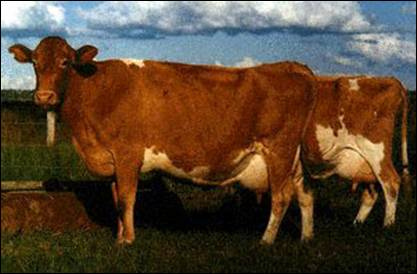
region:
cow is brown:
[8, 32, 335, 241]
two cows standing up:
[7, 38, 409, 247]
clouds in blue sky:
[77, 7, 398, 65]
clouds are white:
[80, 2, 400, 54]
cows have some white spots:
[7, 33, 406, 243]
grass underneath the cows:
[18, 167, 263, 262]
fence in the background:
[3, 86, 100, 218]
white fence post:
[46, 88, 62, 152]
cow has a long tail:
[390, 81, 416, 184]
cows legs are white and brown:
[343, 187, 406, 231]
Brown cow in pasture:
[21, 23, 307, 237]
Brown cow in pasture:
[330, 73, 408, 164]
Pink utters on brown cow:
[339, 159, 410, 201]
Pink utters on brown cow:
[218, 167, 298, 220]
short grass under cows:
[18, 226, 396, 256]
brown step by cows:
[22, 182, 268, 239]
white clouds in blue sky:
[16, 1, 410, 33]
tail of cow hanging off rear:
[290, 78, 333, 154]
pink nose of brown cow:
[22, 82, 47, 99]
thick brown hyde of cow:
[107, 87, 248, 152]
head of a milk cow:
[6, 33, 101, 113]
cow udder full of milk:
[232, 153, 271, 201]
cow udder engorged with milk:
[331, 148, 385, 193]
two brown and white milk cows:
[2, 31, 414, 253]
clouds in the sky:
[0, 1, 415, 71]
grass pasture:
[2, 187, 414, 272]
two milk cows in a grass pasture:
[1, 4, 414, 269]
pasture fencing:
[1, 96, 71, 144]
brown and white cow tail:
[398, 94, 409, 180]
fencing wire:
[0, 116, 47, 126]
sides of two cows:
[8, 35, 407, 241]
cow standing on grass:
[8, 35, 321, 270]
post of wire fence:
[0, 108, 63, 140]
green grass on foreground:
[0, 229, 415, 271]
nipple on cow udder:
[239, 153, 269, 205]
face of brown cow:
[13, 36, 98, 109]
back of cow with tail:
[315, 75, 410, 231]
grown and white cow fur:
[318, 74, 410, 222]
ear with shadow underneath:
[73, 44, 99, 80]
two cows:
[7, 36, 410, 240]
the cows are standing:
[14, 39, 414, 243]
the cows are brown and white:
[7, 38, 415, 244]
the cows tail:
[397, 111, 416, 177]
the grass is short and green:
[72, 233, 190, 269]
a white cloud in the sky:
[92, 3, 353, 35]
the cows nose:
[33, 89, 57, 103]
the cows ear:
[73, 41, 99, 65]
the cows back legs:
[258, 203, 330, 251]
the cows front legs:
[106, 181, 151, 246]